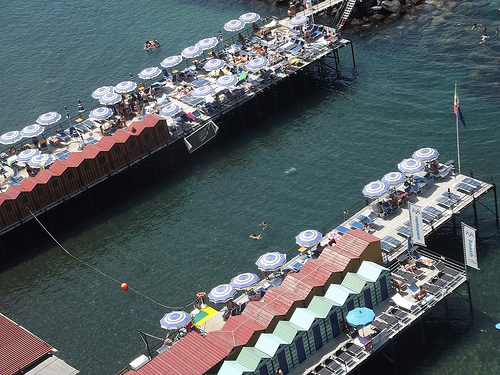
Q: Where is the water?
A: Next to the umbrellas.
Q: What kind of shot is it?
A: Overhead.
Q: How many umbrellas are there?
A: More than five.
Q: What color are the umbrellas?
A: Blue and white.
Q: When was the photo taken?
A: Daytime.